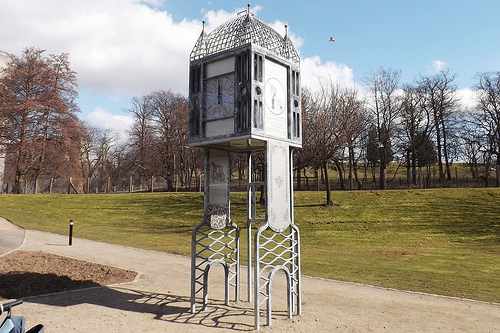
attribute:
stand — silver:
[185, 2, 306, 315]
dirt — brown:
[0, 252, 133, 293]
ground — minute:
[411, 138, 441, 172]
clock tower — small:
[186, 7, 313, 299]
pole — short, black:
[58, 212, 80, 246]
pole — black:
[52, 200, 116, 262]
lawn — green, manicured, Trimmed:
[0, 183, 499, 302]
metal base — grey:
[185, 220, 302, 325]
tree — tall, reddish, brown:
[7, 41, 70, 195]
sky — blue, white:
[1, 2, 498, 168]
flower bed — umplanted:
[1, 248, 143, 305]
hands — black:
[216, 79, 223, 106]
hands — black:
[270, 94, 277, 111]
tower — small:
[186, 27, 303, 331]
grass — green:
[414, 175, 474, 225]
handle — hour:
[212, 75, 226, 108]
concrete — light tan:
[21, 246, 482, 331]